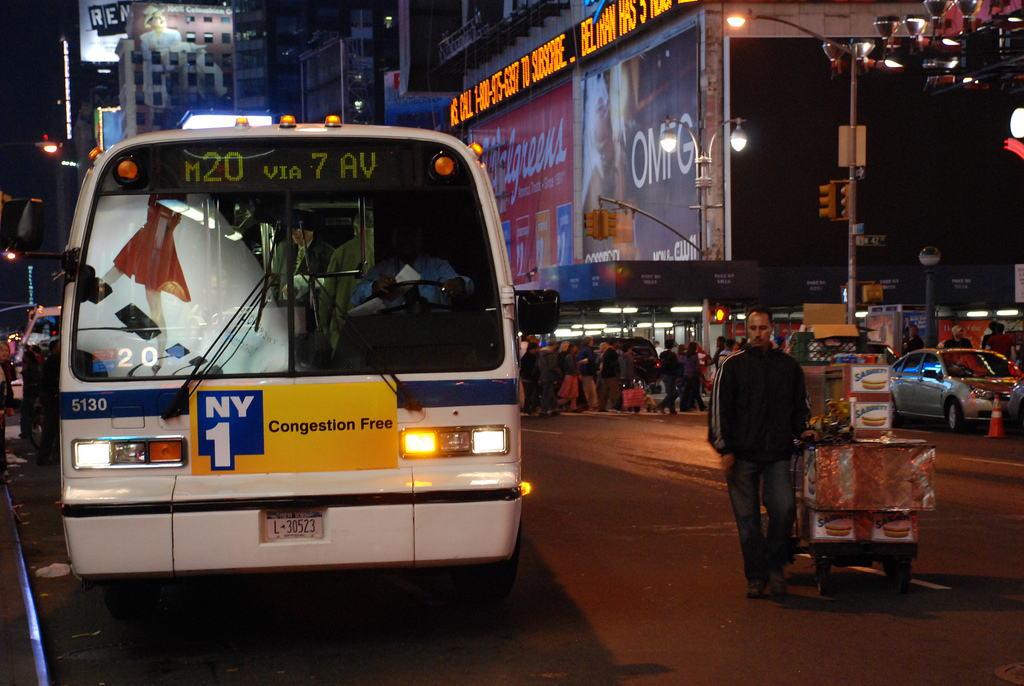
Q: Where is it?
A: This is at the road.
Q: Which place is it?
A: It is a road.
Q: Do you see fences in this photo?
A: No, there are no fences.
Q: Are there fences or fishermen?
A: No, there are no fences or fishermen.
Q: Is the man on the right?
A: Yes, the man is on the right of the image.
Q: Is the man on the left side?
A: No, the man is on the right of the image.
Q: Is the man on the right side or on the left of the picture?
A: The man is on the right of the image.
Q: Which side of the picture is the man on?
A: The man is on the right of the image.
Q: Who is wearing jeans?
A: The man is wearing jeans.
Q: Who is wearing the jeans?
A: The man is wearing jeans.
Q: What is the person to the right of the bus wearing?
A: The man is wearing jeans.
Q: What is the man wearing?
A: The man is wearing jeans.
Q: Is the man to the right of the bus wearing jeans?
A: Yes, the man is wearing jeans.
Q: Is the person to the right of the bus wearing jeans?
A: Yes, the man is wearing jeans.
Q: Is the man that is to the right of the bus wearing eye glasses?
A: No, the man is wearing jeans.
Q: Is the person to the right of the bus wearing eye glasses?
A: No, the man is wearing jeans.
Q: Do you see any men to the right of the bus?
A: Yes, there is a man to the right of the bus.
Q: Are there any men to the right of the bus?
A: Yes, there is a man to the right of the bus.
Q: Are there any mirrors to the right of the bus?
A: No, there is a man to the right of the bus.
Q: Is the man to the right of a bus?
A: Yes, the man is to the right of a bus.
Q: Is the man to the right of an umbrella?
A: No, the man is to the right of a bus.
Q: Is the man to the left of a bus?
A: No, the man is to the right of a bus.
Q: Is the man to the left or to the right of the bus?
A: The man is to the right of the bus.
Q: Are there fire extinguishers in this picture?
A: No, there are no fire extinguishers.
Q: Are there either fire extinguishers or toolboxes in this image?
A: No, there are no fire extinguishers or toolboxes.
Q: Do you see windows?
A: Yes, there is a window.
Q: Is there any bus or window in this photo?
A: Yes, there is a window.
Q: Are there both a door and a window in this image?
A: No, there is a window but no doors.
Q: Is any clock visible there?
A: No, there are no clocks.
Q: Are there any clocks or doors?
A: No, there are no clocks or doors.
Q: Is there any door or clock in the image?
A: No, there are no clocks or doors.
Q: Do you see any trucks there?
A: No, there are no trucks.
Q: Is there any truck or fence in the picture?
A: No, there are no trucks or fences.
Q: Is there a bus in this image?
A: Yes, there is a bus.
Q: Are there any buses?
A: Yes, there is a bus.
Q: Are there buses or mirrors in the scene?
A: Yes, there is a bus.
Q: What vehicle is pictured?
A: The vehicle is a bus.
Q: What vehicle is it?
A: The vehicle is a bus.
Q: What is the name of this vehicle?
A: This is a bus.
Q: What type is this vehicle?
A: This is a bus.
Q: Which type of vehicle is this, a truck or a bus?
A: This is a bus.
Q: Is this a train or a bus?
A: This is a bus.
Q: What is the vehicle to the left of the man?
A: The vehicle is a bus.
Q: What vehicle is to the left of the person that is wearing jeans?
A: The vehicle is a bus.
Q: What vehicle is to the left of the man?
A: The vehicle is a bus.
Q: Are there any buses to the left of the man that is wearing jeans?
A: Yes, there is a bus to the left of the man.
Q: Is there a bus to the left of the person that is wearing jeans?
A: Yes, there is a bus to the left of the man.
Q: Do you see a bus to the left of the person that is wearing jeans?
A: Yes, there is a bus to the left of the man.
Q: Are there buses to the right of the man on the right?
A: No, the bus is to the left of the man.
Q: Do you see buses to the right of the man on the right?
A: No, the bus is to the left of the man.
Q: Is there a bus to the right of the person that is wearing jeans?
A: No, the bus is to the left of the man.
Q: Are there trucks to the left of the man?
A: No, there is a bus to the left of the man.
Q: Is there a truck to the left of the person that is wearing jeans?
A: No, there is a bus to the left of the man.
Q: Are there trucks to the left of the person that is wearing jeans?
A: No, there is a bus to the left of the man.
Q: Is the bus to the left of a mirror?
A: No, the bus is to the left of the man.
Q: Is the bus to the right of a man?
A: No, the bus is to the left of a man.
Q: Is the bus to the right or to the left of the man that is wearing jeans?
A: The bus is to the left of the man.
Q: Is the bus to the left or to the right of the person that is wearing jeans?
A: The bus is to the left of the man.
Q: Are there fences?
A: No, there are no fences.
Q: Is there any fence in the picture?
A: No, there are no fences.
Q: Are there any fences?
A: No, there are no fences.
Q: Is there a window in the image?
A: Yes, there is a window.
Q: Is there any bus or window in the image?
A: Yes, there is a window.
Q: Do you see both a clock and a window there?
A: No, there is a window but no clocks.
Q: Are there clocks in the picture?
A: No, there are no clocks.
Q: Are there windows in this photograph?
A: Yes, there is a window.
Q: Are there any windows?
A: Yes, there is a window.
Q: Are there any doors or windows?
A: Yes, there is a window.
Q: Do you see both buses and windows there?
A: Yes, there are both a window and a bus.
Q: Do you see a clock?
A: No, there are no clocks.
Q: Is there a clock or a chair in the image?
A: No, there are no clocks or chairs.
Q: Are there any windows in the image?
A: Yes, there is a window.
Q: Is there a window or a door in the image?
A: Yes, there is a window.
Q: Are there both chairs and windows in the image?
A: No, there is a window but no chairs.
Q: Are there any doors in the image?
A: No, there are no doors.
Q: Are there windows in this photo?
A: Yes, there is a window.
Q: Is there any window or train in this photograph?
A: Yes, there is a window.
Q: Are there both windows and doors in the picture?
A: No, there is a window but no doors.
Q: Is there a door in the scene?
A: No, there are no doors.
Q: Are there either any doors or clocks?
A: No, there are no doors or clocks.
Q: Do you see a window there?
A: Yes, there is a window.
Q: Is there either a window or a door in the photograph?
A: Yes, there is a window.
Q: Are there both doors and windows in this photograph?
A: No, there is a window but no doors.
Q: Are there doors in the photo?
A: No, there are no doors.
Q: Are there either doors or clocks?
A: No, there are no doors or clocks.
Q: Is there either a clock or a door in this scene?
A: No, there are no doors or clocks.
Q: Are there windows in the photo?
A: Yes, there is a window.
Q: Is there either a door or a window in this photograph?
A: Yes, there is a window.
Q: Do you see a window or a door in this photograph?
A: Yes, there is a window.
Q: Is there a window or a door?
A: Yes, there is a window.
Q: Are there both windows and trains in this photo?
A: No, there is a window but no trains.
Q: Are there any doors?
A: No, there are no doors.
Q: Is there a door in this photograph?
A: No, there are no doors.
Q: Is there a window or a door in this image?
A: Yes, there is a window.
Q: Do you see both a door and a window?
A: No, there is a window but no doors.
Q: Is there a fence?
A: No, there are no fences.